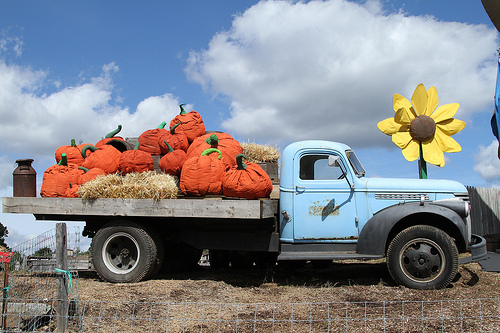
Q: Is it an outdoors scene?
A: Yes, it is outdoors.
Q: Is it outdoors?
A: Yes, it is outdoors.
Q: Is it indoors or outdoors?
A: It is outdoors.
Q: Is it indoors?
A: No, it is outdoors.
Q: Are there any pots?
A: No, there are no pots.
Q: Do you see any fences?
A: Yes, there is a fence.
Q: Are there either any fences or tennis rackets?
A: Yes, there is a fence.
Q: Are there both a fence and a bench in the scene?
A: No, there is a fence but no benches.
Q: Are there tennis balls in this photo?
A: No, there are no tennis balls.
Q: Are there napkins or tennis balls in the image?
A: No, there are no tennis balls or napkins.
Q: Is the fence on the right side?
A: Yes, the fence is on the right of the image.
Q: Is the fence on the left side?
A: No, the fence is on the right of the image.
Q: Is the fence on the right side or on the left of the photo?
A: The fence is on the right of the image.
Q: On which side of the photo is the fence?
A: The fence is on the right of the image.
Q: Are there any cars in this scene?
A: No, there are no cars.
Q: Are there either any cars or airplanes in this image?
A: No, there are no cars or airplanes.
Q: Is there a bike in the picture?
A: No, there are no bikes.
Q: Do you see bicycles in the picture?
A: No, there are no bicycles.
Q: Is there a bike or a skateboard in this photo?
A: No, there are no bikes or skateboards.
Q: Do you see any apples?
A: No, there are no apples.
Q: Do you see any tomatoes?
A: No, there are no tomatoes.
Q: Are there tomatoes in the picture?
A: No, there are no tomatoes.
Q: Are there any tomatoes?
A: No, there are no tomatoes.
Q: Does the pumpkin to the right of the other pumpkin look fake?
A: Yes, the pumpkin is fake.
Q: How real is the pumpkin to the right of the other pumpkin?
A: The pumpkin is fake.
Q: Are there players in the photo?
A: No, there are no players.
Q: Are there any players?
A: No, there are no players.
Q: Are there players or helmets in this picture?
A: No, there are no players or helmets.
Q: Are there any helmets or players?
A: No, there are no players or helmets.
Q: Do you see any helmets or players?
A: No, there are no players or helmets.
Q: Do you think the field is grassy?
A: Yes, the field is grassy.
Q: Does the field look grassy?
A: Yes, the field is grassy.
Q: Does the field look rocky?
A: No, the field is grassy.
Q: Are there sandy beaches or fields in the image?
A: No, there is a field but it is grassy.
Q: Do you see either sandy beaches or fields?
A: No, there is a field but it is grassy.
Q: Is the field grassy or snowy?
A: The field is grassy.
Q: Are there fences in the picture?
A: Yes, there is a fence.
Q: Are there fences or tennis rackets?
A: Yes, there is a fence.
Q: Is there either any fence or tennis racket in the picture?
A: Yes, there is a fence.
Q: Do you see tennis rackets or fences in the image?
A: Yes, there is a fence.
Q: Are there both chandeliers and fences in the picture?
A: No, there is a fence but no chandeliers.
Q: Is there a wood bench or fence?
A: Yes, there is a wood fence.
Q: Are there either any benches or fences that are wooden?
A: Yes, the fence is wooden.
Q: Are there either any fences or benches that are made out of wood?
A: Yes, the fence is made of wood.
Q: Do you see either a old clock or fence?
A: Yes, there is an old fence.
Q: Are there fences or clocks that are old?
A: Yes, the fence is old.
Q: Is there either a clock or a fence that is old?
A: Yes, the fence is old.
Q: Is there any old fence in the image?
A: Yes, there is an old fence.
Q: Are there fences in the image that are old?
A: Yes, there is a fence that is old.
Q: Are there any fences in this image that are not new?
A: Yes, there is a old fence.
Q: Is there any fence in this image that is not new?
A: Yes, there is a old fence.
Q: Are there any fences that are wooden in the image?
A: Yes, there is a wood fence.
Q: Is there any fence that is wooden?
A: Yes, there is a fence that is wooden.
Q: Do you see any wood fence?
A: Yes, there is a fence that is made of wood.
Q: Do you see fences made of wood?
A: Yes, there is a fence that is made of wood.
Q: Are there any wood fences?
A: Yes, there is a fence that is made of wood.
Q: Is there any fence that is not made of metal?
A: Yes, there is a fence that is made of wood.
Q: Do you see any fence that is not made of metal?
A: Yes, there is a fence that is made of wood.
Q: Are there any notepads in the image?
A: No, there are no notepads.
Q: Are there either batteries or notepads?
A: No, there are no notepads or batteries.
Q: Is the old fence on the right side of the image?
A: Yes, the fence is on the right of the image.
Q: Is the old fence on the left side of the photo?
A: No, the fence is on the right of the image.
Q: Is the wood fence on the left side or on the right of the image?
A: The fence is on the right of the image.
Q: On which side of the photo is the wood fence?
A: The fence is on the right of the image.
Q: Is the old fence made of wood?
A: Yes, the fence is made of wood.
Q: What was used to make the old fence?
A: The fence is made of wood.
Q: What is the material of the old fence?
A: The fence is made of wood.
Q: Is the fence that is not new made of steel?
A: No, the fence is made of wood.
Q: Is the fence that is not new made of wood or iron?
A: The fence is made of wood.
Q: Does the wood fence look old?
A: Yes, the fence is old.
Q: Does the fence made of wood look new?
A: No, the fence is old.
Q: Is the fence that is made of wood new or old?
A: The fence is old.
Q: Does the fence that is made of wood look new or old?
A: The fence is old.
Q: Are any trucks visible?
A: Yes, there is a truck.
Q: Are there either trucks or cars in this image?
A: Yes, there is a truck.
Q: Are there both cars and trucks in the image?
A: No, there is a truck but no cars.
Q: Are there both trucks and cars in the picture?
A: No, there is a truck but no cars.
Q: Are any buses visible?
A: No, there are no buses.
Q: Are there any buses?
A: No, there are no buses.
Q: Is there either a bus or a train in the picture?
A: No, there are no buses or trains.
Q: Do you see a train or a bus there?
A: No, there are no buses or trains.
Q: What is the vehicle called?
A: The vehicle is a truck.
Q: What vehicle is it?
A: The vehicle is a truck.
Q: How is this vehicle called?
A: This is a truck.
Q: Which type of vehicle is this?
A: This is a truck.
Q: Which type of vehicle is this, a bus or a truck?
A: This is a truck.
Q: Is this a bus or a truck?
A: This is a truck.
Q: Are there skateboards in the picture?
A: No, there are no skateboards.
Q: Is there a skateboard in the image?
A: No, there are no skateboards.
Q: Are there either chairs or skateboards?
A: No, there are no skateboards or chairs.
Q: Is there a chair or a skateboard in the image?
A: No, there are no skateboards or chairs.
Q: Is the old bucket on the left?
A: Yes, the bucket is on the left of the image.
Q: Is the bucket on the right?
A: No, the bucket is on the left of the image.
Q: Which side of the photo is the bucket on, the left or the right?
A: The bucket is on the left of the image.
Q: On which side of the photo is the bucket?
A: The bucket is on the left of the image.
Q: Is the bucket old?
A: Yes, the bucket is old.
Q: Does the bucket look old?
A: Yes, the bucket is old.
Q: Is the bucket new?
A: No, the bucket is old.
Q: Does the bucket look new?
A: No, the bucket is old.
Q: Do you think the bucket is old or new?
A: The bucket is old.